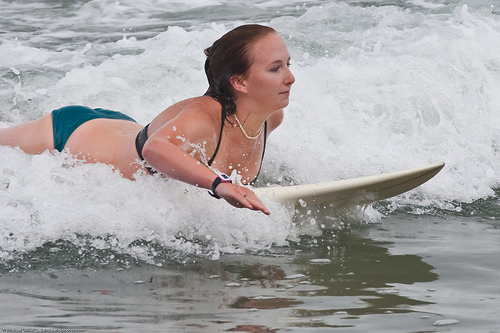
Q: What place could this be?
A: It is an ocean.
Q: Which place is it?
A: It is an ocean.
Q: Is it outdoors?
A: Yes, it is outdoors.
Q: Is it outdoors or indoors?
A: It is outdoors.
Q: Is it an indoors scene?
A: No, it is outdoors.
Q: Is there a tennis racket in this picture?
A: No, there are no rackets.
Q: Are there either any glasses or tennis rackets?
A: No, there are no tennis rackets or glasses.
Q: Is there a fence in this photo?
A: No, there are no fences.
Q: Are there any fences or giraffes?
A: No, there are no fences or giraffes.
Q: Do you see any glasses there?
A: No, there are no glasses.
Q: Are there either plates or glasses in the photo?
A: No, there are no glasses or plates.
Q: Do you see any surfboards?
A: Yes, there is a surfboard.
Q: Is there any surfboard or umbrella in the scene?
A: Yes, there is a surfboard.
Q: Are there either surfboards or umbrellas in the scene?
A: Yes, there is a surfboard.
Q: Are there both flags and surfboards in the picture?
A: No, there is a surfboard but no flags.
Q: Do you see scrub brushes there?
A: No, there are no scrub brushes.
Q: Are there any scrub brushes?
A: No, there are no scrub brushes.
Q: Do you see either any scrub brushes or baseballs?
A: No, there are no scrub brushes or baseballs.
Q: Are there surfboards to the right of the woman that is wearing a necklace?
A: Yes, there is a surfboard to the right of the woman.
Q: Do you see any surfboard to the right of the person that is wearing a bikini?
A: Yes, there is a surfboard to the right of the woman.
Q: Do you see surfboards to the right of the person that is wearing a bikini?
A: Yes, there is a surfboard to the right of the woman.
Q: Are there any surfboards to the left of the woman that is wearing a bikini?
A: No, the surfboard is to the right of the woman.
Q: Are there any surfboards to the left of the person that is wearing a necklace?
A: No, the surfboard is to the right of the woman.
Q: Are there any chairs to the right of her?
A: No, there is a surfboard to the right of the woman.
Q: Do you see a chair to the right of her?
A: No, there is a surfboard to the right of the woman.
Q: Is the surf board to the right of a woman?
A: Yes, the surf board is to the right of a woman.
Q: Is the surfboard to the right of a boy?
A: No, the surfboard is to the right of a woman.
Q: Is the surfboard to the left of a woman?
A: No, the surfboard is to the right of a woman.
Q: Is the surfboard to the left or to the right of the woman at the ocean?
A: The surfboard is to the right of the woman.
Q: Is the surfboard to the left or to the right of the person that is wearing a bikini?
A: The surfboard is to the right of the woman.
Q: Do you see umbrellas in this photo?
A: No, there are no umbrellas.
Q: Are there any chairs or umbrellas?
A: No, there are no umbrellas or chairs.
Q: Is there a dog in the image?
A: No, there are no dogs.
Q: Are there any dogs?
A: No, there are no dogs.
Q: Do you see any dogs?
A: No, there are no dogs.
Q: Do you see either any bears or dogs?
A: No, there are no dogs or bears.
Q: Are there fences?
A: No, there are no fences.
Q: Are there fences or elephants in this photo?
A: No, there are no fences or elephants.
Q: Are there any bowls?
A: No, there are no bowls.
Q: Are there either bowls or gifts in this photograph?
A: No, there are no bowls or gifts.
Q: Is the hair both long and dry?
A: No, the hair is long but wet.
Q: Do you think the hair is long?
A: Yes, the hair is long.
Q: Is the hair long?
A: Yes, the hair is long.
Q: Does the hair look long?
A: Yes, the hair is long.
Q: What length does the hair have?
A: The hair has long length.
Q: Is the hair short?
A: No, the hair is long.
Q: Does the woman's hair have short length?
A: No, the hair is long.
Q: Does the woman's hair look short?
A: No, the hair is long.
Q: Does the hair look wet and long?
A: Yes, the hair is wet and long.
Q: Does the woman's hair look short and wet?
A: No, the hair is wet but long.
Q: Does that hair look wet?
A: Yes, the hair is wet.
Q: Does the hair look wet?
A: Yes, the hair is wet.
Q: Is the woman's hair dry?
A: No, the hair is wet.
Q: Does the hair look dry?
A: No, the hair is wet.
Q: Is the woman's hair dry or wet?
A: The hair is wet.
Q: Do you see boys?
A: No, there are no boys.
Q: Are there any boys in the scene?
A: No, there are no boys.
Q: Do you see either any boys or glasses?
A: No, there are no boys or glasses.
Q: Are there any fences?
A: No, there are no fences.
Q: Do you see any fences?
A: No, there are no fences.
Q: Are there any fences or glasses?
A: No, there are no fences or glasses.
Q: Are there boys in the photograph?
A: No, there are no boys.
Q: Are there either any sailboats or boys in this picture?
A: No, there are no boys or sailboats.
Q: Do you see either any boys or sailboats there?
A: No, there are no boys or sailboats.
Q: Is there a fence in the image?
A: No, there are no fences.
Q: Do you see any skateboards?
A: No, there are no skateboards.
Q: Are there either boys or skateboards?
A: No, there are no skateboards or boys.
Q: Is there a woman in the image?
A: Yes, there is a woman.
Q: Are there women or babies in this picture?
A: Yes, there is a woman.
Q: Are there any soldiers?
A: No, there are no soldiers.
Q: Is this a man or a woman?
A: This is a woman.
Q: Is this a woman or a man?
A: This is a woman.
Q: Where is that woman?
A: The woman is at the ocean.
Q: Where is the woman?
A: The woman is at the ocean.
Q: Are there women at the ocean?
A: Yes, there is a woman at the ocean.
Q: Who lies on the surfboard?
A: The woman lies on the surfboard.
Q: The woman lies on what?
A: The woman lies on the surfboard.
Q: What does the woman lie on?
A: The woman lies on the surfboard.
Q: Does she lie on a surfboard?
A: Yes, the woman lies on a surfboard.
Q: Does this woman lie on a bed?
A: No, the woman lies on a surfboard.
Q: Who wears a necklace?
A: The woman wears a necklace.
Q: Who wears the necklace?
A: The woman wears a necklace.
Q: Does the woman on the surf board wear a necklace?
A: Yes, the woman wears a necklace.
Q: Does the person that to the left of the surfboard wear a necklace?
A: Yes, the woman wears a necklace.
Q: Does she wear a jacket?
A: No, the woman wears a necklace.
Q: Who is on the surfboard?
A: The woman is on the surfboard.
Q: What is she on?
A: The woman is on the surfboard.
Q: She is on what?
A: The woman is on the surfboard.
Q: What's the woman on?
A: The woman is on the surfboard.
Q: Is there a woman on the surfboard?
A: Yes, there is a woman on the surfboard.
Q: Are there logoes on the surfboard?
A: No, there is a woman on the surfboard.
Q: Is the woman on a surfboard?
A: Yes, the woman is on a surfboard.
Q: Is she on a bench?
A: No, the woman is on a surfboard.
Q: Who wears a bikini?
A: The woman wears a bikini.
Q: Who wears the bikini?
A: The woman wears a bikini.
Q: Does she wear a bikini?
A: Yes, the woman wears a bikini.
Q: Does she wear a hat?
A: No, the woman wears a bikini.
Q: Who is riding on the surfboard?
A: The woman is riding on the surfboard.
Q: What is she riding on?
A: The woman is riding on the surf board.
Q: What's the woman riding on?
A: The woman is riding on the surf board.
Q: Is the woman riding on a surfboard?
A: Yes, the woman is riding on a surfboard.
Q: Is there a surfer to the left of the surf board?
A: No, there is a woman to the left of the surf board.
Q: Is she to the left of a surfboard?
A: Yes, the woman is to the left of a surfboard.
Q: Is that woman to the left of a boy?
A: No, the woman is to the left of a surfboard.